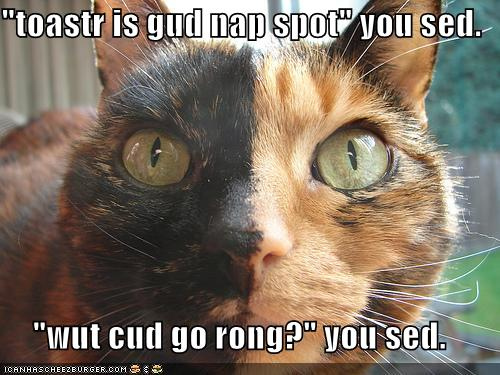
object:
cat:
[1, 0, 500, 375]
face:
[58, 34, 464, 375]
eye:
[121, 127, 194, 187]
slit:
[150, 136, 161, 168]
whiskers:
[14, 160, 499, 373]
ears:
[91, 0, 191, 90]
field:
[437, 248, 499, 342]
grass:
[437, 248, 499, 343]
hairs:
[118, 35, 397, 99]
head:
[56, 0, 464, 375]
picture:
[1, 0, 500, 375]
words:
[33, 321, 446, 355]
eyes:
[314, 126, 390, 190]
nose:
[200, 221, 293, 288]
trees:
[426, 0, 498, 151]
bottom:
[2, 364, 163, 375]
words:
[0, 8, 482, 42]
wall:
[0, 0, 102, 120]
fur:
[56, 201, 462, 373]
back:
[0, 104, 98, 364]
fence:
[444, 149, 499, 248]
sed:
[420, 8, 474, 39]